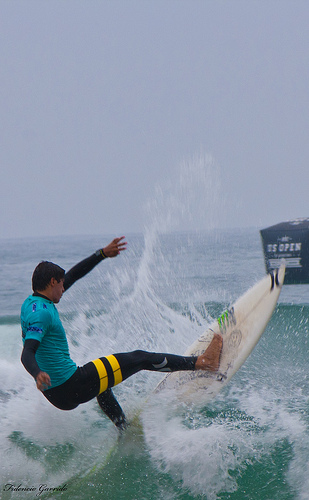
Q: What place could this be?
A: It is an ocean.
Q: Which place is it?
A: It is an ocean.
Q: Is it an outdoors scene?
A: Yes, it is outdoors.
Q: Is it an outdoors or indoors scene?
A: It is outdoors.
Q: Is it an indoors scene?
A: No, it is outdoors.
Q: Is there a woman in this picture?
A: No, there are no women.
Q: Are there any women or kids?
A: No, there are no women or kids.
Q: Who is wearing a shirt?
A: The man is wearing a shirt.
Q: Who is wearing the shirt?
A: The man is wearing a shirt.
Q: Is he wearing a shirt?
A: Yes, the man is wearing a shirt.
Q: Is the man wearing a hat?
A: No, the man is wearing a shirt.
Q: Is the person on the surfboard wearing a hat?
A: No, the man is wearing a shirt.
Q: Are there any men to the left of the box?
A: Yes, there is a man to the left of the box.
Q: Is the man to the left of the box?
A: Yes, the man is to the left of the box.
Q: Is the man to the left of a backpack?
A: No, the man is to the left of the box.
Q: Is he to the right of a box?
A: No, the man is to the left of a box.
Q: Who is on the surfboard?
A: The man is on the surfboard.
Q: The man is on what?
A: The man is on the surfboard.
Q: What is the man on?
A: The man is on the surfboard.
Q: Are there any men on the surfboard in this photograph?
A: Yes, there is a man on the surfboard.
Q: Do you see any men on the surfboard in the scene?
A: Yes, there is a man on the surfboard.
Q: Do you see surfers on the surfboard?
A: No, there is a man on the surfboard.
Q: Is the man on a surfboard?
A: Yes, the man is on a surfboard.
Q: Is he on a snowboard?
A: No, the man is on a surfboard.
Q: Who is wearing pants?
A: The man is wearing pants.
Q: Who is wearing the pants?
A: The man is wearing pants.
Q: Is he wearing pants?
A: Yes, the man is wearing pants.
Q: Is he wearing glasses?
A: No, the man is wearing pants.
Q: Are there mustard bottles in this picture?
A: No, there are no mustard bottles.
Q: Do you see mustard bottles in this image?
A: No, there are no mustard bottles.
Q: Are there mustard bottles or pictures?
A: No, there are no mustard bottles or pictures.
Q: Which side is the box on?
A: The box is on the right of the image.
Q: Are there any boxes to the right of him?
A: Yes, there is a box to the right of the man.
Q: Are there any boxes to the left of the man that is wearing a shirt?
A: No, the box is to the right of the man.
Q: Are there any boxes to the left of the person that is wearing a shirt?
A: No, the box is to the right of the man.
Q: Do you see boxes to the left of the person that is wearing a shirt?
A: No, the box is to the right of the man.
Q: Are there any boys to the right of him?
A: No, there is a box to the right of the man.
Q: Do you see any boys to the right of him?
A: No, there is a box to the right of the man.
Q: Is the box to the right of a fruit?
A: No, the box is to the right of the man.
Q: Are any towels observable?
A: No, there are no towels.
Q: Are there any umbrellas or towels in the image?
A: No, there are no towels or umbrellas.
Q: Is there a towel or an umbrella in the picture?
A: No, there are no towels or umbrellas.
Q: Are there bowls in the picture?
A: No, there are no bowls.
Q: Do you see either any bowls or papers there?
A: No, there are no bowls or papers.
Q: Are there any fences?
A: No, there are no fences.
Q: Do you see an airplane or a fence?
A: No, there are no fences or airplanes.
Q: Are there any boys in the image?
A: No, there are no boys.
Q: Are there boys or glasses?
A: No, there are no boys or glasses.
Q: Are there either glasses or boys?
A: No, there are no boys or glasses.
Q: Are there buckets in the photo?
A: No, there are no buckets.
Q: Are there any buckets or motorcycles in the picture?
A: No, there are no buckets or motorcycles.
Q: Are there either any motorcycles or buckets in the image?
A: No, there are no buckets or motorcycles.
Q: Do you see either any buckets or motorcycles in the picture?
A: No, there are no buckets or motorcycles.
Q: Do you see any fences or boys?
A: No, there are no fences or boys.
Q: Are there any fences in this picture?
A: No, there are no fences.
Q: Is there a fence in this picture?
A: No, there are no fences.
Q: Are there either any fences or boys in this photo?
A: No, there are no fences or boys.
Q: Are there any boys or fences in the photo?
A: No, there are no fences or boys.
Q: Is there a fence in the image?
A: No, there are no fences.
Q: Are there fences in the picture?
A: No, there are no fences.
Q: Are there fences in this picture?
A: No, there are no fences.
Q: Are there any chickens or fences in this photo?
A: No, there are no fences or chickens.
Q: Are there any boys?
A: No, there are no boys.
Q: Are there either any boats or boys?
A: No, there are no boys or boats.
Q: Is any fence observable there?
A: No, there are no fences.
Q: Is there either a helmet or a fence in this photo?
A: No, there are no fences or helmets.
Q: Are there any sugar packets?
A: No, there are no sugar packets.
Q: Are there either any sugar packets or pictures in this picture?
A: No, there are no sugar packets or pictures.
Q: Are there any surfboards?
A: Yes, there is a surfboard.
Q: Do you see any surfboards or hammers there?
A: Yes, there is a surfboard.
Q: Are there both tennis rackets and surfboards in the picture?
A: No, there is a surfboard but no rackets.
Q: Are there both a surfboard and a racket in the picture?
A: No, there is a surfboard but no rackets.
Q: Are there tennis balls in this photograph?
A: No, there are no tennis balls.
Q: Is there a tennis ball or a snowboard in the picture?
A: No, there are no tennis balls or snowboards.